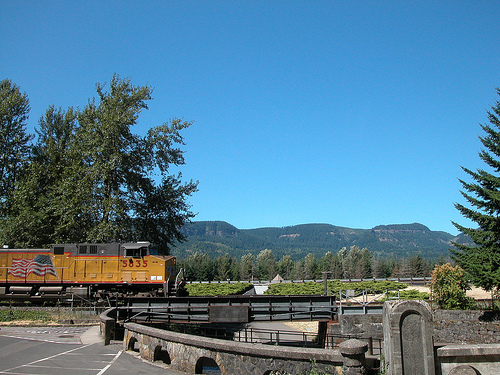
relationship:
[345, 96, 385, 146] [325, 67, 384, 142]
sky has part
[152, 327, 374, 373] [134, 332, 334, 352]
line has edge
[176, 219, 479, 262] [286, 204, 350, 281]
hill has part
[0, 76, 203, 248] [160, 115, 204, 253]
tree has part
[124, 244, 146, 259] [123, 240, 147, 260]
window has part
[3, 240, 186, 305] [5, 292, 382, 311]
train travelling down tracks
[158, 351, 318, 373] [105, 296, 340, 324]
river below bridge